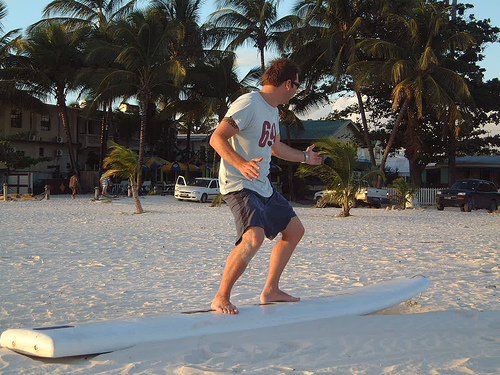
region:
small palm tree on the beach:
[90, 143, 157, 216]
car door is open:
[167, 163, 207, 208]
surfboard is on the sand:
[1, 267, 433, 360]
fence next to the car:
[387, 183, 468, 211]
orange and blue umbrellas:
[139, 150, 211, 205]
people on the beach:
[38, 166, 136, 204]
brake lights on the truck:
[348, 182, 409, 214]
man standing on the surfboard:
[197, 35, 363, 334]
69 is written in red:
[261, 119, 279, 153]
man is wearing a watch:
[288, 142, 318, 173]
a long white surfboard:
[0, 265, 430, 366]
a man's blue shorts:
[226, 186, 296, 241]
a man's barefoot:
[260, 283, 297, 303]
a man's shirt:
[215, 91, 282, 199]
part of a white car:
[170, 172, 216, 202]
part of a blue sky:
[470, 0, 495, 16]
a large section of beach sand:
[0, 197, 496, 372]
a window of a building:
[33, 111, 53, 127]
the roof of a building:
[455, 151, 496, 162]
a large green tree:
[27, 0, 201, 221]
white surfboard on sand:
[3, 265, 442, 363]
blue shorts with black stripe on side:
[213, 175, 306, 247]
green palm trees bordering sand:
[3, 2, 234, 191]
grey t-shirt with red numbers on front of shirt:
[202, 85, 286, 202]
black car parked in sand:
[430, 174, 496, 222]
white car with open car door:
[166, 165, 221, 206]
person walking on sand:
[56, 164, 87, 201]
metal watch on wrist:
[295, 148, 312, 169]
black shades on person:
[288, 76, 302, 93]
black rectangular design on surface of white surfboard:
[23, 317, 81, 337]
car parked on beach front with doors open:
[175, 172, 225, 202]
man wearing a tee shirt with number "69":
[218, 90, 280, 195]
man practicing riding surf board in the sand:
[2, 272, 437, 361]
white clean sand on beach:
[2, 189, 498, 373]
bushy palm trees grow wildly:
[2, 1, 473, 218]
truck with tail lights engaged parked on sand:
[313, 178, 393, 208]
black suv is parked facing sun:
[433, 178, 498, 213]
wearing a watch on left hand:
[291, 145, 320, 163]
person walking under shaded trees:
[66, 172, 83, 199]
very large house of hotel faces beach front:
[1, 81, 176, 198]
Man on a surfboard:
[200, 48, 343, 320]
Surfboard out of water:
[24, 267, 439, 343]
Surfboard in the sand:
[26, 260, 498, 361]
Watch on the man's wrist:
[305, 138, 310, 171]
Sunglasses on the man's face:
[288, 79, 305, 92]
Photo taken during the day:
[12, 6, 494, 364]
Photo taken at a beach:
[18, 32, 493, 367]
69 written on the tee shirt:
[250, 118, 290, 151]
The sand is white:
[31, 195, 483, 368]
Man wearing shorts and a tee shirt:
[197, 69, 322, 303]